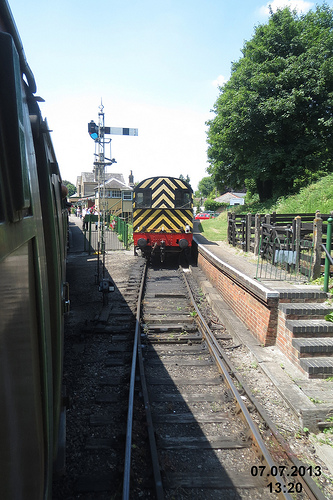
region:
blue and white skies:
[132, 82, 180, 121]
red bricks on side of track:
[237, 306, 269, 326]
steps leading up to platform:
[281, 288, 328, 378]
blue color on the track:
[111, 364, 137, 442]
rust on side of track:
[231, 431, 260, 452]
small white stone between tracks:
[238, 393, 253, 402]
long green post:
[320, 214, 331, 283]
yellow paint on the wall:
[95, 200, 134, 206]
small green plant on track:
[184, 311, 198, 320]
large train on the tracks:
[123, 172, 196, 280]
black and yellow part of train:
[136, 172, 195, 257]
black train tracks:
[107, 241, 300, 498]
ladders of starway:
[281, 295, 331, 373]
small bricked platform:
[192, 223, 331, 352]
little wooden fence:
[227, 214, 331, 281]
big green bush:
[205, 5, 331, 209]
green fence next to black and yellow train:
[68, 208, 127, 251]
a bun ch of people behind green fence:
[70, 207, 114, 228]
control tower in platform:
[83, 103, 140, 188]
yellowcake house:
[65, 174, 134, 215]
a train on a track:
[113, 169, 298, 353]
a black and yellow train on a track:
[117, 162, 190, 281]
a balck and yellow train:
[122, 158, 240, 324]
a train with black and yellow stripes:
[97, 158, 233, 277]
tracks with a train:
[93, 177, 211, 346]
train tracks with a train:
[76, 171, 212, 322]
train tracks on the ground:
[106, 216, 262, 419]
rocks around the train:
[90, 253, 204, 399]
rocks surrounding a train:
[97, 265, 222, 459]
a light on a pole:
[86, 111, 144, 221]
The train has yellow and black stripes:
[113, 162, 208, 235]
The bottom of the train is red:
[120, 220, 206, 256]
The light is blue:
[83, 104, 107, 146]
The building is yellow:
[59, 159, 138, 231]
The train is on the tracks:
[114, 166, 205, 268]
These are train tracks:
[111, 249, 280, 498]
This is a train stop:
[198, 202, 332, 371]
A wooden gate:
[223, 192, 332, 278]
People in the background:
[68, 193, 122, 225]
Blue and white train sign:
[96, 113, 148, 146]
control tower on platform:
[83, 101, 141, 214]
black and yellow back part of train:
[128, 176, 196, 243]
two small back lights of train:
[135, 240, 189, 249]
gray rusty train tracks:
[88, 240, 283, 495]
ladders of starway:
[279, 287, 330, 378]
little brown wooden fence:
[227, 211, 329, 280]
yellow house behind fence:
[64, 186, 132, 220]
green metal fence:
[72, 215, 133, 253]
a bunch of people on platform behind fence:
[68, 202, 112, 229]